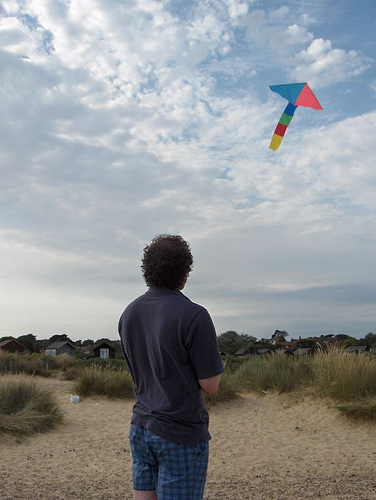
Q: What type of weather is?
A: It is cloudy.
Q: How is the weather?
A: It is cloudy.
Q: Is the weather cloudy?
A: Yes, it is cloudy.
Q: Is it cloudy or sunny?
A: It is cloudy.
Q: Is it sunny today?
A: No, it is cloudy.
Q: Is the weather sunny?
A: No, it is cloudy.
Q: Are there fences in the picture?
A: No, there are no fences.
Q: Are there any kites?
A: Yes, there is a kite.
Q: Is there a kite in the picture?
A: Yes, there is a kite.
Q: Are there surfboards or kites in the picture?
A: Yes, there is a kite.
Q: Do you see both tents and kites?
A: No, there is a kite but no tents.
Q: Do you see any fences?
A: No, there are no fences.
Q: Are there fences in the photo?
A: No, there are no fences.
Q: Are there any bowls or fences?
A: No, there are no fences or bowls.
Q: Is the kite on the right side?
A: Yes, the kite is on the right of the image.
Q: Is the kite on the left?
A: No, the kite is on the right of the image.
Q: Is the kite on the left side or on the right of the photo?
A: The kite is on the right of the image.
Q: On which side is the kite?
A: The kite is on the right of the image.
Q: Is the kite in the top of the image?
A: Yes, the kite is in the top of the image.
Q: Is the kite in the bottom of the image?
A: No, the kite is in the top of the image.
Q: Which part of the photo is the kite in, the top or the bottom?
A: The kite is in the top of the image.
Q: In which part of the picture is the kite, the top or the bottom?
A: The kite is in the top of the image.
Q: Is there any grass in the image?
A: Yes, there is grass.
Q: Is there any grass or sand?
A: Yes, there is grass.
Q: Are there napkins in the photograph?
A: No, there are no napkins.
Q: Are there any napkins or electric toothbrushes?
A: No, there are no napkins or electric toothbrushes.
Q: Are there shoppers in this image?
A: No, there are no shoppers.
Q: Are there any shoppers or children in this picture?
A: No, there are no shoppers or children.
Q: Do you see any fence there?
A: No, there are no fences.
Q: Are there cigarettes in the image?
A: No, there are no cigarettes.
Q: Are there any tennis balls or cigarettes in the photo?
A: No, there are no cigarettes or tennis balls.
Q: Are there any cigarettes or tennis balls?
A: No, there are no cigarettes or tennis balls.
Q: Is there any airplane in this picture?
A: No, there are no airplanes.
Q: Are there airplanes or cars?
A: No, there are no airplanes or cars.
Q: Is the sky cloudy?
A: Yes, the sky is cloudy.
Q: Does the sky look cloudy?
A: Yes, the sky is cloudy.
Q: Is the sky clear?
A: No, the sky is cloudy.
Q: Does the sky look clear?
A: No, the sky is cloudy.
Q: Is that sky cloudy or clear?
A: The sky is cloudy.